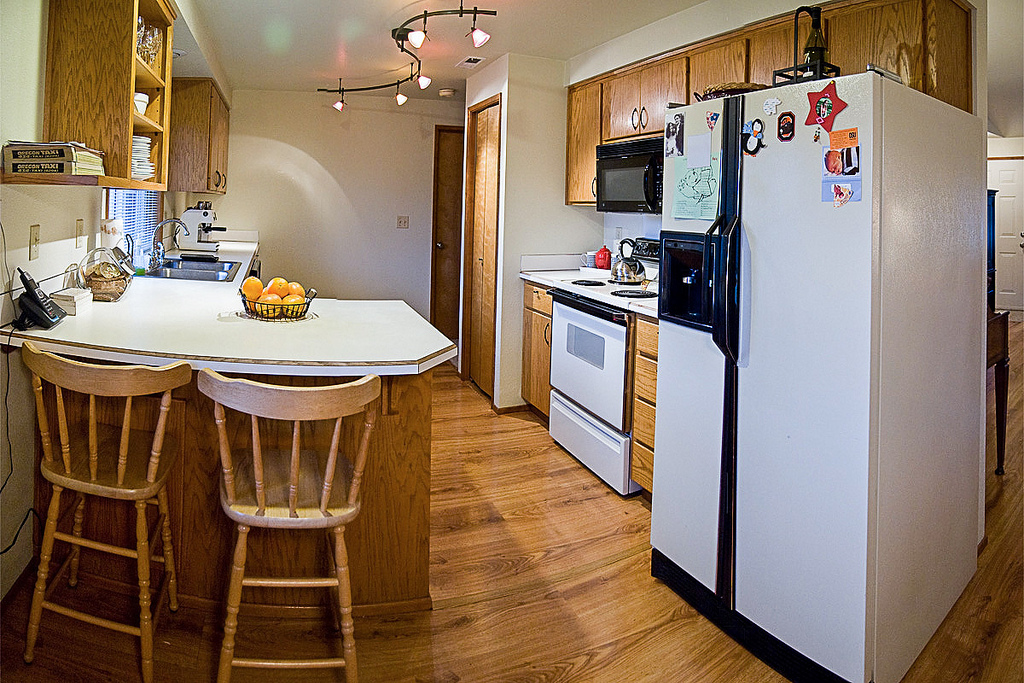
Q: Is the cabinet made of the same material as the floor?
A: Yes, both the cabinet and the floor are made of wood.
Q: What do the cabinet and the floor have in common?
A: The material, both the cabinet and the floor are wooden.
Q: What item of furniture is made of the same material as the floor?
A: The cabinet is made of the same material as the floor.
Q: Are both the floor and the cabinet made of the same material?
A: Yes, both the floor and the cabinet are made of wood.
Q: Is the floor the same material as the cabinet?
A: Yes, both the floor and the cabinet are made of wood.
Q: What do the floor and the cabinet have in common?
A: The material, both the floor and the cabinet are wooden.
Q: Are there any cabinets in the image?
A: Yes, there is a cabinet.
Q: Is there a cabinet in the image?
A: Yes, there is a cabinet.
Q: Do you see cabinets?
A: Yes, there is a cabinet.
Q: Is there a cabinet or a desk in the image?
A: Yes, there is a cabinet.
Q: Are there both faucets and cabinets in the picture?
A: Yes, there are both a cabinet and a faucet.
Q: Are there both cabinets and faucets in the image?
A: Yes, there are both a cabinet and a faucet.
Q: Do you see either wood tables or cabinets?
A: Yes, there is a wood cabinet.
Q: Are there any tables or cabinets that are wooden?
A: Yes, the cabinet is wooden.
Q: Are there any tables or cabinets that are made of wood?
A: Yes, the cabinet is made of wood.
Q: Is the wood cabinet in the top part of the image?
A: Yes, the cabinet is in the top of the image.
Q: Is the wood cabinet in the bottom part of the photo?
A: No, the cabinet is in the top of the image.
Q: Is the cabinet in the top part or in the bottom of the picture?
A: The cabinet is in the top of the image.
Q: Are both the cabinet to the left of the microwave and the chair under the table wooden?
A: Yes, both the cabinet and the chair are wooden.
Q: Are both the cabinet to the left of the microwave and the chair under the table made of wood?
A: Yes, both the cabinet and the chair are made of wood.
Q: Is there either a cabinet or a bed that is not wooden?
A: No, there is a cabinet but it is wooden.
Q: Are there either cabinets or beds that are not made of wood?
A: No, there is a cabinet but it is made of wood.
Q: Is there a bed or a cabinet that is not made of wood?
A: No, there is a cabinet but it is made of wood.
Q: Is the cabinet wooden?
A: Yes, the cabinet is wooden.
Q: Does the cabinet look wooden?
A: Yes, the cabinet is wooden.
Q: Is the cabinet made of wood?
A: Yes, the cabinet is made of wood.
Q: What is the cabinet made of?
A: The cabinet is made of wood.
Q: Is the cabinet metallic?
A: No, the cabinet is wooden.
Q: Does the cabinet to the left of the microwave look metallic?
A: No, the cabinet is wooden.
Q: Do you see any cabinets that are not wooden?
A: No, there is a cabinet but it is wooden.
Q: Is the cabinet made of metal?
A: No, the cabinet is made of wood.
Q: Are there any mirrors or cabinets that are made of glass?
A: No, there is a cabinet but it is made of wood.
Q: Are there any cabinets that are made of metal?
A: No, there is a cabinet but it is made of wood.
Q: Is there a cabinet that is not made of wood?
A: No, there is a cabinet but it is made of wood.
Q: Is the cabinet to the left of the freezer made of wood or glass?
A: The cabinet is made of wood.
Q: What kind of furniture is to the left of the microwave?
A: The piece of furniture is a cabinet.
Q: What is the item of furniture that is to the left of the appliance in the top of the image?
A: The piece of furniture is a cabinet.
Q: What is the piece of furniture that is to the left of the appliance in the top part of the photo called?
A: The piece of furniture is a cabinet.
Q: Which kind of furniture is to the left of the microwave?
A: The piece of furniture is a cabinet.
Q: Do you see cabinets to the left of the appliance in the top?
A: Yes, there is a cabinet to the left of the microwave.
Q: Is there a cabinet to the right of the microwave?
A: No, the cabinet is to the left of the microwave.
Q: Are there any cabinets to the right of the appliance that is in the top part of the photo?
A: No, the cabinet is to the left of the microwave.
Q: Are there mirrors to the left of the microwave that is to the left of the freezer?
A: No, there is a cabinet to the left of the microwave.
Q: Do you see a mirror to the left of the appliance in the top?
A: No, there is a cabinet to the left of the microwave.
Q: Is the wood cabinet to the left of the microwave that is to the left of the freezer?
A: Yes, the cabinet is to the left of the microwave.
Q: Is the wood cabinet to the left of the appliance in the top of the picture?
A: Yes, the cabinet is to the left of the microwave.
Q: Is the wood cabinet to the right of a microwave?
A: No, the cabinet is to the left of a microwave.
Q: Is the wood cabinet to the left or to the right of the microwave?
A: The cabinet is to the left of the microwave.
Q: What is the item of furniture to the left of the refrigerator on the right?
A: The piece of furniture is a cabinet.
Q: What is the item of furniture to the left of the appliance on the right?
A: The piece of furniture is a cabinet.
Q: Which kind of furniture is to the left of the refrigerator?
A: The piece of furniture is a cabinet.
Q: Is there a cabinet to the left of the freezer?
A: Yes, there is a cabinet to the left of the freezer.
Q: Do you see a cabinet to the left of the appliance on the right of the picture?
A: Yes, there is a cabinet to the left of the freezer.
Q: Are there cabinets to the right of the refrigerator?
A: No, the cabinet is to the left of the refrigerator.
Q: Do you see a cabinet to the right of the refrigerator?
A: No, the cabinet is to the left of the refrigerator.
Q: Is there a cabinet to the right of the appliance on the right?
A: No, the cabinet is to the left of the refrigerator.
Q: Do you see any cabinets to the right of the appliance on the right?
A: No, the cabinet is to the left of the refrigerator.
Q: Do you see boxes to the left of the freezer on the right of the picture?
A: No, there is a cabinet to the left of the fridge.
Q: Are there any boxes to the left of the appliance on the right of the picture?
A: No, there is a cabinet to the left of the fridge.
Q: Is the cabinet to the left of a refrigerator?
A: Yes, the cabinet is to the left of a refrigerator.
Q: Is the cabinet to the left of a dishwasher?
A: No, the cabinet is to the left of a refrigerator.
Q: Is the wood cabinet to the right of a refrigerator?
A: No, the cabinet is to the left of a refrigerator.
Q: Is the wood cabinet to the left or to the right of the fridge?
A: The cabinet is to the left of the fridge.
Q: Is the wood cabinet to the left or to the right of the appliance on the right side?
A: The cabinet is to the left of the fridge.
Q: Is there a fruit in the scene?
A: Yes, there is a fruit.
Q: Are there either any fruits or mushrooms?
A: Yes, there is a fruit.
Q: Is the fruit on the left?
A: Yes, the fruit is on the left of the image.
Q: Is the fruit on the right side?
A: No, the fruit is on the left of the image.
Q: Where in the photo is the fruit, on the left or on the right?
A: The fruit is on the left of the image.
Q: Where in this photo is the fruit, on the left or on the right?
A: The fruit is on the left of the image.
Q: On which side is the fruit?
A: The fruit is on the left of the image.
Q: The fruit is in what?
A: The fruit is in the bowl.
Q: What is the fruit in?
A: The fruit is in the bowl.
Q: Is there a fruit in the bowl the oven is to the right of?
A: Yes, there is a fruit in the bowl.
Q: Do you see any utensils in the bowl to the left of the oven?
A: No, there is a fruit in the bowl.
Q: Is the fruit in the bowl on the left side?
A: Yes, the fruit is in the bowl.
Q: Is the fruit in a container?
A: No, the fruit is in the bowl.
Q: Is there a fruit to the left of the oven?
A: Yes, there is a fruit to the left of the oven.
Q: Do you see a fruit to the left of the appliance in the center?
A: Yes, there is a fruit to the left of the oven.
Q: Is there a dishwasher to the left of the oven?
A: No, there is a fruit to the left of the oven.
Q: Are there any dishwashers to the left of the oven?
A: No, there is a fruit to the left of the oven.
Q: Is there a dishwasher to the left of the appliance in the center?
A: No, there is a fruit to the left of the oven.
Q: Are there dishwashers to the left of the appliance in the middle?
A: No, there is a fruit to the left of the oven.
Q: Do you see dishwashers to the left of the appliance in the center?
A: No, there is a fruit to the left of the oven.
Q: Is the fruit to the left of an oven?
A: Yes, the fruit is to the left of an oven.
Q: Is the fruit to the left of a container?
A: No, the fruit is to the left of an oven.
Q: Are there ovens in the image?
A: Yes, there is an oven.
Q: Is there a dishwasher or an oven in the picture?
A: Yes, there is an oven.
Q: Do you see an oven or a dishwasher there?
A: Yes, there is an oven.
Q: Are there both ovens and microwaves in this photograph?
A: Yes, there are both an oven and a microwave.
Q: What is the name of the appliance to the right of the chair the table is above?
A: The appliance is an oven.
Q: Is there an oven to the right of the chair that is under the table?
A: Yes, there is an oven to the right of the chair.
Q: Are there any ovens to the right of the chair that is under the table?
A: Yes, there is an oven to the right of the chair.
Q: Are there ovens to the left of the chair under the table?
A: No, the oven is to the right of the chair.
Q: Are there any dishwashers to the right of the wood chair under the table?
A: No, there is an oven to the right of the chair.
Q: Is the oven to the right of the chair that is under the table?
A: Yes, the oven is to the right of the chair.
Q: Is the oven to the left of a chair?
A: No, the oven is to the right of a chair.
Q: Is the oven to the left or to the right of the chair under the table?
A: The oven is to the right of the chair.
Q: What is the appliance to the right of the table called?
A: The appliance is an oven.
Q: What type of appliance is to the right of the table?
A: The appliance is an oven.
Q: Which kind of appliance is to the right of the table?
A: The appliance is an oven.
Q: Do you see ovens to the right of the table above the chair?
A: Yes, there is an oven to the right of the table.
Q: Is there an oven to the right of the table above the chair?
A: Yes, there is an oven to the right of the table.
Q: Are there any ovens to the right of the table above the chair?
A: Yes, there is an oven to the right of the table.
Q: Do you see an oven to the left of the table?
A: No, the oven is to the right of the table.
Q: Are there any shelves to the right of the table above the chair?
A: No, there is an oven to the right of the table.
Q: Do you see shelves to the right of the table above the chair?
A: No, there is an oven to the right of the table.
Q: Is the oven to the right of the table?
A: Yes, the oven is to the right of the table.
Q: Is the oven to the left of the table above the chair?
A: No, the oven is to the right of the table.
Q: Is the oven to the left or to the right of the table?
A: The oven is to the right of the table.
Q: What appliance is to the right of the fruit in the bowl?
A: The appliance is an oven.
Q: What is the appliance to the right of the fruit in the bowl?
A: The appliance is an oven.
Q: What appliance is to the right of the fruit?
A: The appliance is an oven.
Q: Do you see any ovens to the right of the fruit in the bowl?
A: Yes, there is an oven to the right of the fruit.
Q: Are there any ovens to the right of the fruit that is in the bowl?
A: Yes, there is an oven to the right of the fruit.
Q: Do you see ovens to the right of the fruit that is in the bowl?
A: Yes, there is an oven to the right of the fruit.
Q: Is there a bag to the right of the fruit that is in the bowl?
A: No, there is an oven to the right of the fruit.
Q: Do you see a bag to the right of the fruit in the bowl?
A: No, there is an oven to the right of the fruit.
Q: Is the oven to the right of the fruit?
A: Yes, the oven is to the right of the fruit.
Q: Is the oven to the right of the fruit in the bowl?
A: Yes, the oven is to the right of the fruit.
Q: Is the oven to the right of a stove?
A: No, the oven is to the right of the fruit.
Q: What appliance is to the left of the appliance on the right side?
A: The appliance is an oven.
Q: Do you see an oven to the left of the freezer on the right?
A: Yes, there is an oven to the left of the fridge.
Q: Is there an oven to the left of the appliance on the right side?
A: Yes, there is an oven to the left of the fridge.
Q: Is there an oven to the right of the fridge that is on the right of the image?
A: No, the oven is to the left of the refrigerator.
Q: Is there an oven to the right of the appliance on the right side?
A: No, the oven is to the left of the refrigerator.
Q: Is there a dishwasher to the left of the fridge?
A: No, there is an oven to the left of the fridge.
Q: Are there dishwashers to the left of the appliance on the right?
A: No, there is an oven to the left of the fridge.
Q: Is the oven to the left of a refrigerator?
A: Yes, the oven is to the left of a refrigerator.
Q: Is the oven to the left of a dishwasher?
A: No, the oven is to the left of a refrigerator.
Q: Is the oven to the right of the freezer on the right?
A: No, the oven is to the left of the freezer.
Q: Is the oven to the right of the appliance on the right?
A: No, the oven is to the left of the freezer.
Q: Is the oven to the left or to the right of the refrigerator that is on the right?
A: The oven is to the left of the freezer.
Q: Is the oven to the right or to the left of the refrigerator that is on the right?
A: The oven is to the left of the freezer.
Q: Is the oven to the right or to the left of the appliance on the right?
A: The oven is to the left of the freezer.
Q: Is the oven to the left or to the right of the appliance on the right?
A: The oven is to the left of the freezer.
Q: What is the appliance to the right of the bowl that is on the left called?
A: The appliance is an oven.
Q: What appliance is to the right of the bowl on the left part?
A: The appliance is an oven.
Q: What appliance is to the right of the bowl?
A: The appliance is an oven.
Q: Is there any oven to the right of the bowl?
A: Yes, there is an oven to the right of the bowl.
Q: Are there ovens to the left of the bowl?
A: No, the oven is to the right of the bowl.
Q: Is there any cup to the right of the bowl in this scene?
A: No, there is an oven to the right of the bowl.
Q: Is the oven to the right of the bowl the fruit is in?
A: Yes, the oven is to the right of the bowl.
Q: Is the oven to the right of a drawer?
A: No, the oven is to the right of the bowl.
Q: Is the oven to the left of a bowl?
A: No, the oven is to the right of a bowl.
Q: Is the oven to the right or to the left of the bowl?
A: The oven is to the right of the bowl.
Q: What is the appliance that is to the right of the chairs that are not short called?
A: The appliance is an oven.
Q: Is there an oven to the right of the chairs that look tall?
A: Yes, there is an oven to the right of the chairs.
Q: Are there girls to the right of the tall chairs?
A: No, there is an oven to the right of the chairs.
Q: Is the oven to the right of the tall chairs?
A: Yes, the oven is to the right of the chairs.